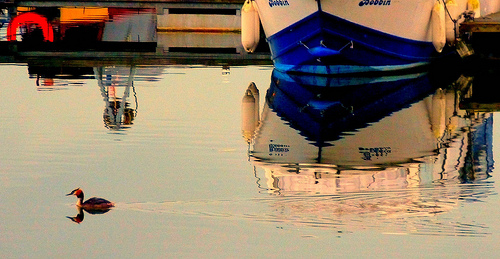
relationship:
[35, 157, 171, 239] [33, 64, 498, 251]
bird in water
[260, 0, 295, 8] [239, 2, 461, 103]
wording on boat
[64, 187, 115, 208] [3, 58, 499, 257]
bird in water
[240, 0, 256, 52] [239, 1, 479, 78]
bouy on boat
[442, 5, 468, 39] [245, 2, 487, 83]
rope on boat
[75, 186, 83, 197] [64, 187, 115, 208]
red spot on bird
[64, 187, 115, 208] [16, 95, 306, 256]
bird on ground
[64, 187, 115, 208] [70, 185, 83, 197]
bird with spot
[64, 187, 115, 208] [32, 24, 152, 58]
bird on ground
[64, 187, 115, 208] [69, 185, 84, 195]
bird with spot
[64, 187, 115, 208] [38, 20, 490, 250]
bird on ground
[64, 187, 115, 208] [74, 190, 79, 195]
bird with red spot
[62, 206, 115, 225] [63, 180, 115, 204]
reflection of bird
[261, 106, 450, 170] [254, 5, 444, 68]
reflection of boat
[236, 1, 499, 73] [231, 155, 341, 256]
boat in water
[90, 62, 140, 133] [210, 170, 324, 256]
reflection on water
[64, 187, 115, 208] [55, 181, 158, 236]
bird has feathers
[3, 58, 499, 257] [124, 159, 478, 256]
water covering surface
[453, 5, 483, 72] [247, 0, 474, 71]
pier beside boat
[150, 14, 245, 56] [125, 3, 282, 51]
stripe on structure